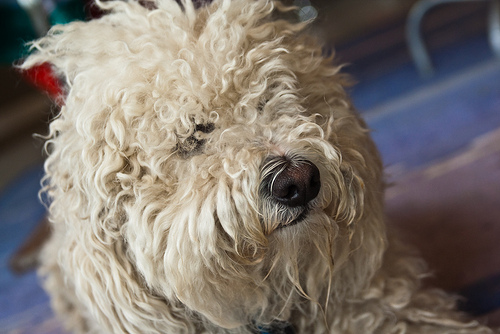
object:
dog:
[17, 0, 409, 333]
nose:
[268, 159, 323, 207]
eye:
[175, 113, 218, 156]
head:
[15, 0, 398, 331]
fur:
[16, 0, 492, 334]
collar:
[136, 279, 325, 333]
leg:
[318, 275, 495, 333]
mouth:
[264, 208, 316, 234]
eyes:
[171, 117, 217, 158]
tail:
[35, 237, 90, 334]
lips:
[266, 209, 314, 230]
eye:
[255, 94, 275, 113]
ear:
[51, 70, 138, 196]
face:
[134, 69, 383, 296]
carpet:
[0, 38, 499, 333]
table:
[315, 0, 490, 81]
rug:
[378, 140, 497, 326]